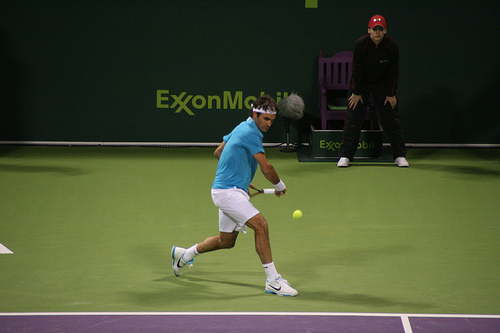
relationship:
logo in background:
[153, 83, 252, 113] [0, 2, 498, 142]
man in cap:
[337, 11, 412, 169] [366, 14, 388, 31]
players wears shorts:
[170, 94, 302, 302] [212, 185, 263, 233]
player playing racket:
[170, 94, 302, 302] [249, 183, 284, 199]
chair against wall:
[315, 48, 375, 128] [0, 2, 498, 142]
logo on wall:
[153, 83, 252, 113] [0, 2, 498, 142]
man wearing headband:
[170, 94, 302, 302] [249, 102, 275, 114]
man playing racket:
[170, 94, 302, 302] [249, 183, 284, 199]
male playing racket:
[170, 94, 302, 302] [249, 183, 284, 199]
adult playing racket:
[170, 94, 302, 302] [249, 183, 284, 199]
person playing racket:
[170, 94, 302, 302] [249, 183, 284, 199]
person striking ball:
[170, 94, 302, 302] [292, 206, 305, 221]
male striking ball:
[170, 94, 302, 302] [292, 206, 305, 221]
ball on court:
[292, 206, 305, 221] [3, 145, 497, 330]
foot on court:
[263, 275, 300, 298] [3, 145, 497, 330]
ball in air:
[292, 206, 305, 221] [278, 195, 317, 231]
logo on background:
[153, 83, 252, 113] [0, 2, 498, 142]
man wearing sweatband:
[170, 94, 302, 302] [249, 102, 275, 114]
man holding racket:
[170, 94, 302, 302] [249, 183, 284, 199]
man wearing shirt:
[170, 94, 302, 302] [213, 117, 267, 191]